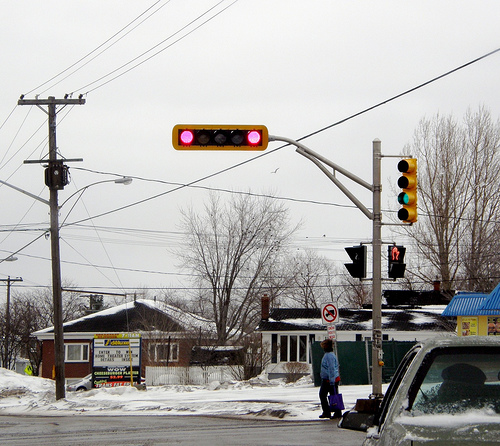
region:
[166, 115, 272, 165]
traffic lights hanging over street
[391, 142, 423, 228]
traffic lights in a panel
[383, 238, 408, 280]
pedestrian lights for crossing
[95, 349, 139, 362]
lettering on the stand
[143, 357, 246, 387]
fence in front of building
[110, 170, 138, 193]
light for the street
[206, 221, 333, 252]
birds on electrical lines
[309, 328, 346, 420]
a person walking under a traffic light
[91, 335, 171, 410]
a sign placed in front of a house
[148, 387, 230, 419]
snow covering the ground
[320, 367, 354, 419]
a person carrying a blue bag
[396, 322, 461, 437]
a car stopped at a traffic light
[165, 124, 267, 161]
red lights lighting a traffic light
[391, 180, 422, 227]
green light lighting a traffic light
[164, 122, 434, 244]
traffic lights connected to a post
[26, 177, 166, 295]
power lines crossing over a neigbhorhood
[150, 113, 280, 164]
THIS TRAFFIC LIGHT IS WIDE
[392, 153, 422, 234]
THIS TRAFFIC LIGHT IS TALL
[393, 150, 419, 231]
THE TRAFFIC LIGHT IS PAINTED YELLOW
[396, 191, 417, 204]
THE LIGHT IS GREEN INDICATING THAT TRAFFIC MAY GO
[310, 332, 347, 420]
THE WOMAN IS WALKING IN THE SNOW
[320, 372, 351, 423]
THE WOMAN IS WEARING BLACK PANTS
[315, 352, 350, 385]
THE WOMAN IS WEARING A BLUE JACKET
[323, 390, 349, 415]
THE WOMAN IS CARRYING A BLUE BAG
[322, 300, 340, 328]
THE SIGN SAYS NO TRUCKS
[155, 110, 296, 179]
A traffic light in the photo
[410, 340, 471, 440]
A car in the photo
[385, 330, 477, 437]
A car covered by snow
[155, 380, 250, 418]
Snow on the road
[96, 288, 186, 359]
A house in the background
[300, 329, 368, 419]
A person on the road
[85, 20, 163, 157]
Power cables in the photo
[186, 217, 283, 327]
A tree in the photo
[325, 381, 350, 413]
A blue bag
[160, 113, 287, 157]
two red lights on the traffic light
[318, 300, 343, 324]
red, white, and black sign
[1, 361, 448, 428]
white snow on the ground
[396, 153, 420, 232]
row of four whites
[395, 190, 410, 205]
traffic light shining green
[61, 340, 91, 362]
window on the side of the building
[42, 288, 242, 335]
snow on top of the roof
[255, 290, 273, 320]
chimney on the roof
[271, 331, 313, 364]
white lines on the window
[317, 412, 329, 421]
foot lifted off the ground